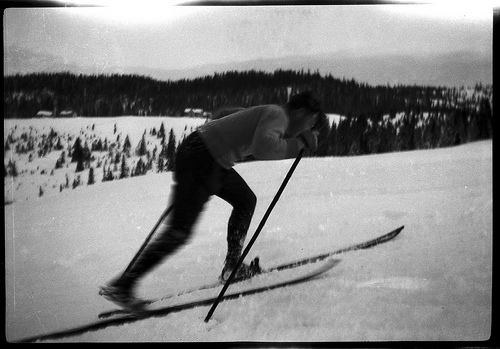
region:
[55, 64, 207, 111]
row of trees covered in leaves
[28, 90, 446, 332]
man on pair skis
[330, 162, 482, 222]
ground covered in snow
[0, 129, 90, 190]
trees covered in snow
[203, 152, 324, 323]
black metal ski pole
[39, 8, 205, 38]
bright sun shining in sky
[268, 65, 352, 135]
man with dark hair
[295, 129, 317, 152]
ski pole strap on hand of man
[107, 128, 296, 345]
man in black pants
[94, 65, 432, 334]
man walking in snow with skis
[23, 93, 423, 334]
Man cross-country skiing up hill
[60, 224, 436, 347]
Man's skies are long and black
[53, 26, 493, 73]
Low lying clouds just above trees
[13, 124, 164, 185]
Sparsely planted pine trees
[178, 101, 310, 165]
Man is wearing a sweater to keep warm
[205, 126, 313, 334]
Man's ski pole is long and black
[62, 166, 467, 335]
Snow looks fresh and powdery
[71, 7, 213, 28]
Small ray of sunshine just above clouds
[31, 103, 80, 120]
Two buildings are in far back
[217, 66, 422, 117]
Section of thick forested pine trees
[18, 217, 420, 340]
A pair of skis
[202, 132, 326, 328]
The right ski pole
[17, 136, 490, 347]
Snow covered hill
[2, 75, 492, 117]
Tree line in the distance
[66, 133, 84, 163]
A coniferous pine tree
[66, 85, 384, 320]
A cross country skier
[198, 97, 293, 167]
A medium colored warm sweater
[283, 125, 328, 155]
A toasty glove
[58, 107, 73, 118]
A snow covered building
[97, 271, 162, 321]
A ski boot in motion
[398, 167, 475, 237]
the snow is white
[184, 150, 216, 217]
person is wearing pants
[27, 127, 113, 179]
trees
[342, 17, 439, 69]
clouds in the sky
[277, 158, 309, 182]
ski pole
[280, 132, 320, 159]
person is holding ski pole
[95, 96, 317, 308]
the person is skiing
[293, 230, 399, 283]
the person is wearing skiis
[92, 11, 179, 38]
the light of the sun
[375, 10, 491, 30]
the sun in the sky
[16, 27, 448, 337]
black and white photograph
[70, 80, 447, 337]
cross country skier going uphill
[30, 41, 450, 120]
trees covering hills in the distance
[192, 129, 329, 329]
ski pole held by skier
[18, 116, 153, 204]
trees scattered on hill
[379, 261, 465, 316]
ground covered with snow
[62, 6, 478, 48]
light reflecting in the sky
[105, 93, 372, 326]
skier bent over pushing uphill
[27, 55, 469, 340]
only one skier in photograph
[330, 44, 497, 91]
mountains in the far distance